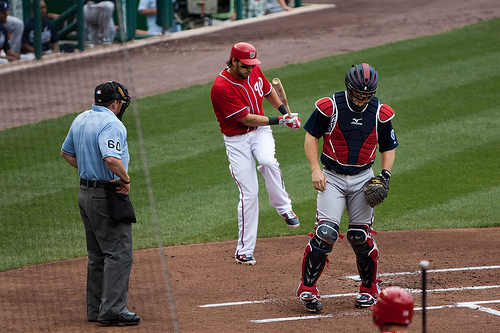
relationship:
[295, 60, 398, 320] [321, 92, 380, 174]
catcher wearing vest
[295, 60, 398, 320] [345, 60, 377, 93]
catcher wearing helmet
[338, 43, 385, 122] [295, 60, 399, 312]
head of catcher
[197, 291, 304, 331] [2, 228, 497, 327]
lines in dirt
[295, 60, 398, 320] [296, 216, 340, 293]
catcher wearing leg pad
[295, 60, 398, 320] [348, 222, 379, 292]
catcher wearing leg pad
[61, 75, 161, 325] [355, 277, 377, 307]
umpire wearing sneakers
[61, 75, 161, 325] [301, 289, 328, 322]
umpire wearing sneakers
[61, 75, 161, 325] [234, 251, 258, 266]
umpire wearing shoe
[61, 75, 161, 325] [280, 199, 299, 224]
umpire wearing sneakers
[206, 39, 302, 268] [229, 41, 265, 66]
player wearing helmet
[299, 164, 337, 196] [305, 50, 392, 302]
hand on person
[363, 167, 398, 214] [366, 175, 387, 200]
glove on hand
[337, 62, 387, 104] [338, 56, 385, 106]
helmet on head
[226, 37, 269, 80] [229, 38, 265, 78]
helmet on head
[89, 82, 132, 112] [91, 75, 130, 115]
helmet on head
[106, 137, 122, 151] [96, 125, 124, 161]
number on sleeve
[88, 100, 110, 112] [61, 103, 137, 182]
collar on shirt